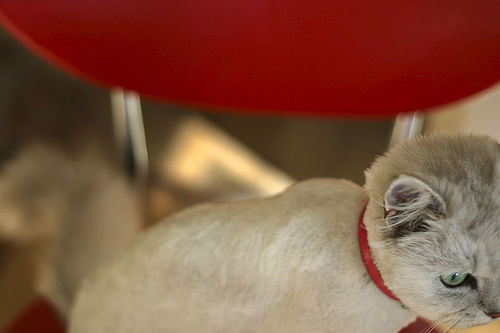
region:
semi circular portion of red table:
[5, 4, 497, 116]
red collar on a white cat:
[337, 188, 418, 316]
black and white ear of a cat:
[378, 168, 460, 238]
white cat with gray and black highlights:
[62, 123, 494, 326]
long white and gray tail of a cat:
[2, 148, 143, 311]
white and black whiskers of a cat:
[409, 307, 474, 330]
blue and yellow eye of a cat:
[432, 265, 476, 296]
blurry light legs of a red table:
[96, 92, 159, 182]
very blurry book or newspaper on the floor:
[157, 116, 299, 208]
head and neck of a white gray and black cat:
[359, 120, 498, 327]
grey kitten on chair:
[130, 136, 499, 331]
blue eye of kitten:
[433, 265, 475, 284]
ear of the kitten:
[381, 180, 450, 230]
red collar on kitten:
[363, 262, 388, 288]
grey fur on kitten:
[296, 243, 316, 268]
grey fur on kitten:
[276, 291, 297, 306]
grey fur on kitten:
[215, 284, 225, 297]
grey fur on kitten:
[326, 284, 358, 310]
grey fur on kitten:
[301, 228, 328, 258]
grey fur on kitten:
[168, 270, 199, 300]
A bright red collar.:
[357, 200, 386, 311]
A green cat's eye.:
[436, 263, 471, 290]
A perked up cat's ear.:
[378, 168, 452, 242]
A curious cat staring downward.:
[34, 122, 497, 332]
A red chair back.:
[5, 2, 498, 83]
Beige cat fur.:
[190, 239, 318, 301]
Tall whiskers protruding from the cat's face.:
[423, 305, 469, 332]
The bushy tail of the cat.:
[1, 124, 144, 316]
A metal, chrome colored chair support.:
[110, 91, 152, 173]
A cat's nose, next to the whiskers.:
[475, 295, 498, 320]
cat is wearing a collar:
[322, 132, 417, 327]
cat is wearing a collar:
[347, 182, 415, 317]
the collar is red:
[333, 164, 400, 309]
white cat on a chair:
[23, 126, 497, 319]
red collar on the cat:
[342, 190, 393, 308]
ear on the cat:
[376, 162, 446, 227]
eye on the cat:
[440, 262, 480, 292]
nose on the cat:
[481, 297, 496, 317]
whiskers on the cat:
[415, 297, 475, 332]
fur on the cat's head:
[440, 144, 492, 211]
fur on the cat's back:
[247, 208, 322, 300]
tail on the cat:
[8, 139, 120, 254]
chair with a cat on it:
[85, 1, 445, 116]